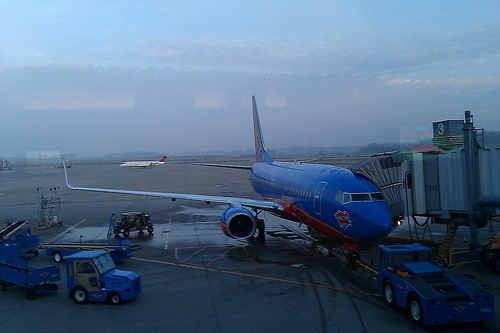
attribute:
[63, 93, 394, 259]
plane — blue, large, parked, red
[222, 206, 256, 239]
engine — blue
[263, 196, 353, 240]
stripe — red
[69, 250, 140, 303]
vehicle — little, blue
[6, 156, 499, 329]
tarmac — concrete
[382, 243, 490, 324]
cart — blue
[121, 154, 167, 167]
plane — white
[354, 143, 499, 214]
walkway — existing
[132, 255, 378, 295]
line — yellow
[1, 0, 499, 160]
sky — overcast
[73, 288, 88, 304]
tire — round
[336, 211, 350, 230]
symbol — red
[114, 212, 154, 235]
vehicle — black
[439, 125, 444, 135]
number — white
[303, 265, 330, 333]
line — black